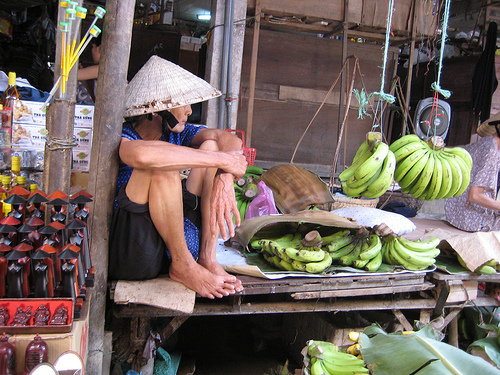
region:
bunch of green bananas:
[254, 228, 336, 280]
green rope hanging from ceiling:
[373, 4, 400, 109]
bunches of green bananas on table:
[247, 220, 444, 282]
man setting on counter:
[102, 56, 254, 313]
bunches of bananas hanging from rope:
[344, 117, 480, 209]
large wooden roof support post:
[82, 0, 137, 287]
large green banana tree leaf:
[358, 331, 497, 373]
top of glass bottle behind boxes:
[0, 66, 22, 99]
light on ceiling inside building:
[190, 7, 216, 26]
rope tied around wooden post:
[44, 132, 81, 159]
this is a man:
[118, 23, 248, 300]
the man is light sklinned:
[159, 178, 176, 226]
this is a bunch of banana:
[408, 130, 463, 197]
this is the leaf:
[396, 333, 446, 373]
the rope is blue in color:
[377, 15, 389, 68]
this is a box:
[11, 100, 38, 148]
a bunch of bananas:
[340, 132, 393, 199]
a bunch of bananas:
[390, 130, 472, 201]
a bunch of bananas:
[259, 230, 330, 275]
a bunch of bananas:
[318, 225, 381, 270]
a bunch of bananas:
[381, 228, 436, 269]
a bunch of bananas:
[306, 336, 366, 372]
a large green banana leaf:
[356, 327, 496, 372]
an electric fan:
[410, 95, 450, 140]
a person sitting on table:
[115, 50, 246, 296]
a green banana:
[354, 143, 387, 180]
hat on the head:
[114, 51, 232, 133]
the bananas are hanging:
[343, 137, 463, 217]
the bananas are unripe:
[400, 153, 450, 189]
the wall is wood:
[262, 78, 337, 165]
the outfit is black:
[124, 233, 146, 263]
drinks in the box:
[38, 281, 56, 327]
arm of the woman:
[126, 146, 241, 173]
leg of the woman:
[155, 154, 223, 290]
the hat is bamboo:
[128, 45, 188, 110]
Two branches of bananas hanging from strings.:
[339, 83, 476, 201]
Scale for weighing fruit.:
[414, 90, 454, 147]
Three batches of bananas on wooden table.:
[251, 223, 442, 278]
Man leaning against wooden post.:
[83, 35, 247, 305]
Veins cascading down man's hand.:
[210, 172, 232, 203]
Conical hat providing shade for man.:
[118, 45, 226, 128]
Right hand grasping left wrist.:
[207, 147, 254, 184]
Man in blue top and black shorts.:
[110, 47, 243, 299]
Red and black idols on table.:
[1, 185, 95, 335]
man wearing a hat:
[113, 55, 243, 302]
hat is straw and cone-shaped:
[121, 54, 223, 121]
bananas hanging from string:
[336, 5, 478, 202]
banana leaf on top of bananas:
[303, 326, 499, 374]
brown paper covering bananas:
[398, 215, 498, 280]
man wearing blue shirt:
[112, 54, 249, 298]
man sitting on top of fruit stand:
[101, 49, 499, 370]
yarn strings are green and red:
[363, 0, 448, 144]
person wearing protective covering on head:
[116, 53, 226, 120]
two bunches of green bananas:
[335, 130, 475, 202]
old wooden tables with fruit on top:
[109, 270, 499, 364]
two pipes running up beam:
[216, 0, 239, 129]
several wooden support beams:
[40, 0, 252, 373]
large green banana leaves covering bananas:
[353, 318, 498, 373]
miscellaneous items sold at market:
[1, 0, 108, 371]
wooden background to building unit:
[246, 0, 498, 188]